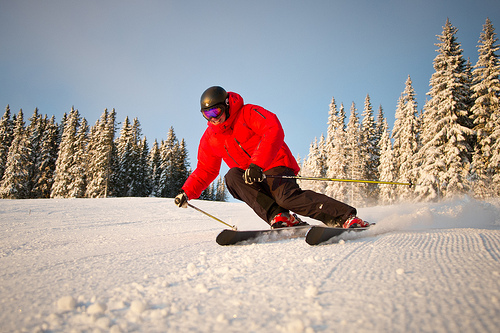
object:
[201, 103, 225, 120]
goggles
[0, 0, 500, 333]
background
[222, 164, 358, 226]
sweatpants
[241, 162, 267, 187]
glove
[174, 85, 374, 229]
man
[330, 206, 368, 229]
shoes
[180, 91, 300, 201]
jacket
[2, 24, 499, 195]
snow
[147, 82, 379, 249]
man wearing helmet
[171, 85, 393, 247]
man wearing goggles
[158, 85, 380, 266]
man wearing jacket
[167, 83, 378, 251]
man wearing pants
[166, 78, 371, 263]
man using pole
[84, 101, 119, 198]
pine trees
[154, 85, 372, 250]
man wearing glove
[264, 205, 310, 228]
shoe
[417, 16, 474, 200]
evergreen trees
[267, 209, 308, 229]
left foot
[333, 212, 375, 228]
right foot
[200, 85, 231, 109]
helmet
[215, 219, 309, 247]
skis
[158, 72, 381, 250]
man wearing sneakers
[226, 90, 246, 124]
red hood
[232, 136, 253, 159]
black zipper